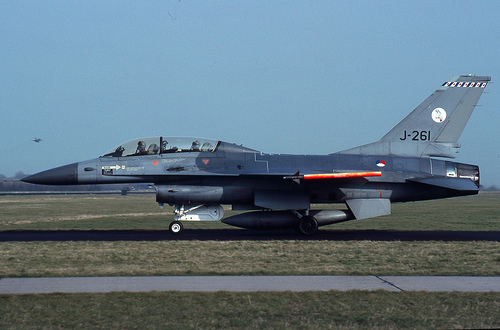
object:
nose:
[20, 162, 80, 186]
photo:
[0, 0, 499, 330]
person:
[133, 139, 149, 156]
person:
[174, 139, 203, 152]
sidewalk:
[0, 274, 499, 295]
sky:
[0, 1, 499, 188]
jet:
[3, 74, 492, 237]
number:
[409, 128, 419, 142]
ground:
[0, 194, 498, 328]